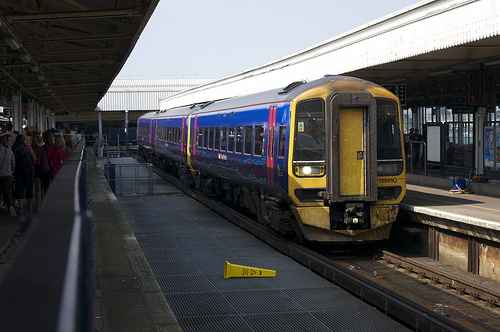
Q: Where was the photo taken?
A: At a train station.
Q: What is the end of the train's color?
A: Yellow.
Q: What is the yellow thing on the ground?
A: A cone.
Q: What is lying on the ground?
A: Yellow safety cone.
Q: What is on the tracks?
A: Train.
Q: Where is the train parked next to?
A: Platform.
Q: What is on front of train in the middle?
A: Door.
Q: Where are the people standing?
A: On platform.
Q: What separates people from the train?
A: Railing.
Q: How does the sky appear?
A: Clear.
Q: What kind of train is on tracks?
A: Passenger.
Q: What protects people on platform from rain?
A: Roof.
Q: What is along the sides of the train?
A: WIndows.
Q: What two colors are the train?
A: Blue, Yellow.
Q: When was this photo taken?
A: Daytime.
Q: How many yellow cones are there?
A: One.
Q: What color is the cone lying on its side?
A: Yellow.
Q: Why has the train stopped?
A: Station.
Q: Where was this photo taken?
A: Train station.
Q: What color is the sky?
A: Blue.